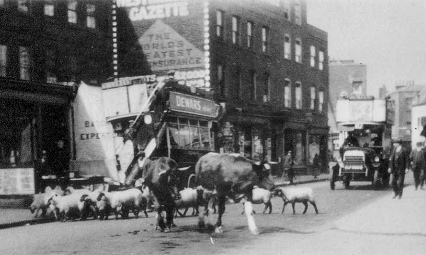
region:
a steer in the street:
[196, 145, 283, 235]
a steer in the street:
[143, 157, 191, 237]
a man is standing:
[387, 138, 408, 197]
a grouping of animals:
[31, 185, 149, 223]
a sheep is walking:
[273, 183, 318, 215]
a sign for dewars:
[168, 90, 217, 117]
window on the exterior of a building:
[213, 8, 224, 39]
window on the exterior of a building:
[230, 14, 238, 46]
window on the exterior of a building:
[15, 40, 32, 80]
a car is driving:
[325, 119, 398, 192]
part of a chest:
[220, 161, 247, 220]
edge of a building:
[162, 6, 224, 74]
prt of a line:
[343, 184, 373, 222]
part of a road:
[329, 184, 351, 215]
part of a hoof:
[246, 223, 256, 242]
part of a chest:
[231, 175, 257, 202]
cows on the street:
[135, 134, 281, 234]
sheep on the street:
[23, 161, 147, 231]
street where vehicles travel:
[69, 210, 314, 251]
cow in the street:
[137, 154, 278, 231]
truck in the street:
[330, 87, 390, 188]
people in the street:
[387, 134, 420, 194]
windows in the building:
[216, 8, 321, 68]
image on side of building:
[118, 2, 200, 75]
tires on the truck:
[328, 160, 383, 189]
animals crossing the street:
[257, 182, 320, 221]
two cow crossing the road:
[135, 149, 278, 249]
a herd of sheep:
[31, 178, 331, 223]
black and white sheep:
[271, 179, 323, 212]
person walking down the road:
[383, 135, 404, 200]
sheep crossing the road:
[22, 174, 334, 233]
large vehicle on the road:
[320, 109, 396, 194]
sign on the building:
[163, 81, 226, 120]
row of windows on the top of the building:
[209, 5, 328, 74]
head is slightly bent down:
[159, 166, 185, 199]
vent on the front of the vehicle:
[340, 146, 369, 174]